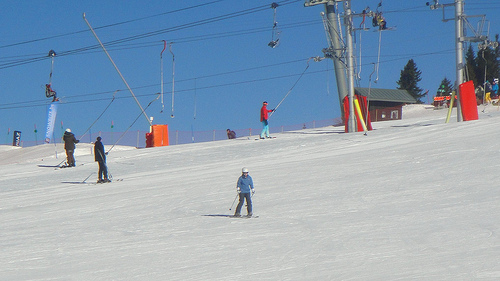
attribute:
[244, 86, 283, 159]
man — working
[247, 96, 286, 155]
he — wearing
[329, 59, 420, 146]
building — small, brown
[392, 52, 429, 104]
tree — evergreen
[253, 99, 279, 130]
coat — red, black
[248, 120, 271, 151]
pant — blue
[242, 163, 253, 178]
helmet — white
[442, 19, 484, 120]
pole — gray, yellow, metal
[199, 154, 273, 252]
person — skiing, wearing, standing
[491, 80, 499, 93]
sign — blue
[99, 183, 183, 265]
plain — snowy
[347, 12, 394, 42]
people — riding, holding up, standing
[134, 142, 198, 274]
slope — snow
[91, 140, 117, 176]
clothe — black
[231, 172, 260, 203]
jacket — blue